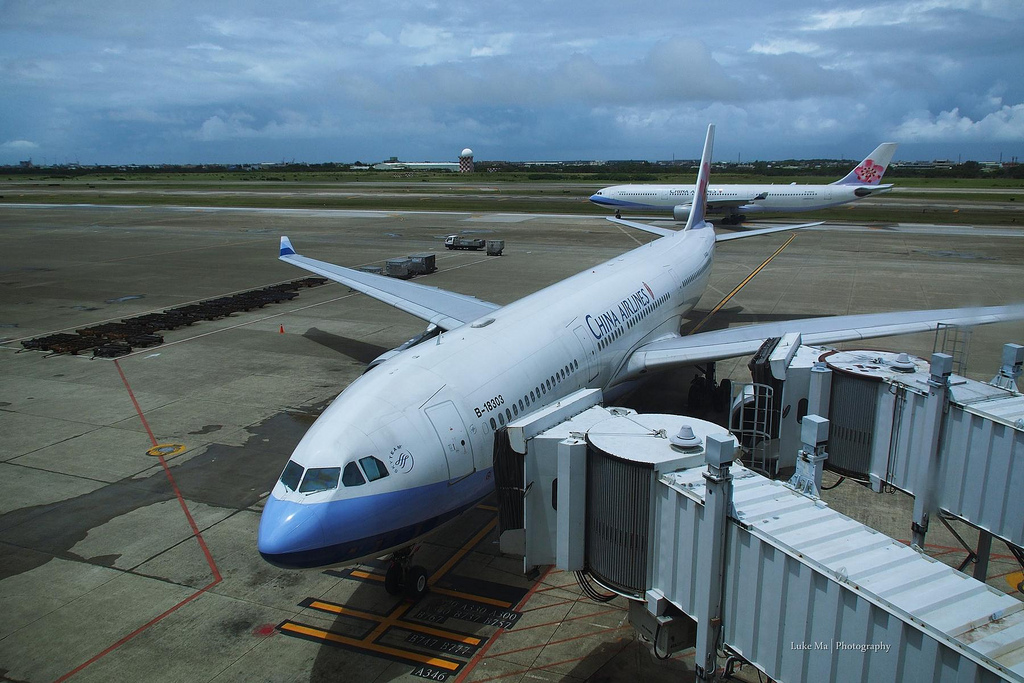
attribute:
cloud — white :
[208, 16, 327, 49]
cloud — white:
[748, 28, 824, 65]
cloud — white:
[890, 101, 1011, 162]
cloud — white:
[391, 19, 458, 67]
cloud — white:
[370, 19, 502, 74]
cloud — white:
[890, 95, 1016, 152]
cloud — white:
[199, 112, 334, 154]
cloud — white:
[4, 119, 43, 169]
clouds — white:
[8, 0, 1020, 154]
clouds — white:
[8, 0, 1018, 182]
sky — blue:
[8, 3, 1020, 176]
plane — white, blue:
[261, 115, 1020, 558]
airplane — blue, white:
[265, 128, 1020, 600]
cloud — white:
[748, 28, 833, 65]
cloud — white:
[907, 95, 1011, 167]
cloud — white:
[387, 6, 454, 65]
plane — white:
[147, 149, 914, 653]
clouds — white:
[175, 106, 495, 154]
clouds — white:
[250, 39, 376, 98]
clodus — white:
[451, 33, 875, 127]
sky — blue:
[2, 3, 1020, 198]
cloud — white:
[75, 18, 534, 124]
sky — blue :
[2, 5, 990, 165]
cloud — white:
[375, 61, 620, 146]